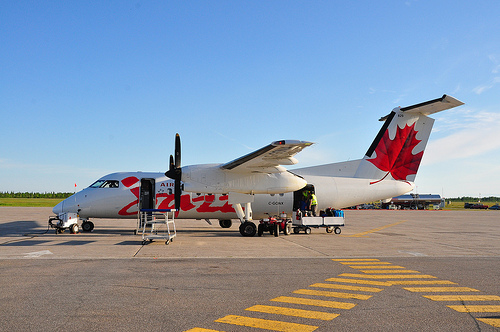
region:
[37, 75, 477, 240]
A small red and white airplane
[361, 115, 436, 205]
A red maple leaf on the tail of an airplane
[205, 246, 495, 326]
Yellow lines painted on pavement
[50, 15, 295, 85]
A clear blue sky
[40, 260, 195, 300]
A gray asphalt ground surface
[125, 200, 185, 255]
A metal cart with wheels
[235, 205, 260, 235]
A black wheel on an airplane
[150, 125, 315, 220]
An airplane's wing and propeller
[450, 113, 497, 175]
White wispy clouds in the sky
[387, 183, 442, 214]
A metal silver tank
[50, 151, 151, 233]
front of a plane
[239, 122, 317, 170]
wing of a plane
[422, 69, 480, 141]
wing of a plane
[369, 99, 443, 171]
wing of a plane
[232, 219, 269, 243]
wheel of a plane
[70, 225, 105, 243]
tire of a plane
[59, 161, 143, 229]
cockpit of a plane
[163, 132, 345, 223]
body of a plane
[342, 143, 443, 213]
tail of a plane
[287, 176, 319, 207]
door of a plane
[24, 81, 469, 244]
an airplane on a tarmac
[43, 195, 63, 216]
the nosecone of an airplane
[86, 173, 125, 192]
the cockpit of an airplane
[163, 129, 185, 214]
the propeller of an airplane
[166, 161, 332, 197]
the engine of an airplane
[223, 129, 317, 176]
the wing of an airplane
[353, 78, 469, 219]
the tail of an airplane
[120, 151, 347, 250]
the fuselage of an airplane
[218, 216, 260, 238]
the landing gear of an airplane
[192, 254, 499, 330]
yellow lines painted on ground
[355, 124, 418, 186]
red leaf on plane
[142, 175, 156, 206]
doorway on the plane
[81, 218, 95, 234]
front wheels on plane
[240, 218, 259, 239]
left wheel on plane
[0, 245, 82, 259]
white arrow on ground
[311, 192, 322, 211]
worker at the airline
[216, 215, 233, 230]
black tire on plane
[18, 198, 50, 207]
green grass on ground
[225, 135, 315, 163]
left wing on plane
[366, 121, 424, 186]
a red leaf on the tail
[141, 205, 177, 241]
a luggage cart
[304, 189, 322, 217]
a man loading luggage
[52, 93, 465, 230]
a small white airplane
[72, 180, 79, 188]
an orange flag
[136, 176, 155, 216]
the plane door is open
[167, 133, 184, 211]
propeller on the wing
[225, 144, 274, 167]
a black stripe on the wing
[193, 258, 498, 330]
yellow stripes on the ground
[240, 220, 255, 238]
a wheel on the landing gear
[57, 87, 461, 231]
white and red plane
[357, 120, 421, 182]
red maple leaf on the plane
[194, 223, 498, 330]
yellow lines on the pavement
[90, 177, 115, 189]
cockpit windows on the plane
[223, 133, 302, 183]
wing on the plane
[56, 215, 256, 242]
black tires on the plane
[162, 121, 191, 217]
black propeller on the plane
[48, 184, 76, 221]
nose of the plane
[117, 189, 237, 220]
red script on the plane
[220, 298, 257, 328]
yellow line on the pavement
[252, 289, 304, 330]
yellow line on the pavement